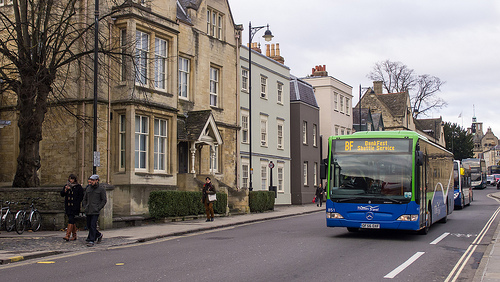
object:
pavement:
[2, 200, 322, 252]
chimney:
[372, 79, 385, 96]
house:
[335, 77, 437, 137]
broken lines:
[383, 250, 427, 277]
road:
[35, 243, 307, 281]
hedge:
[250, 188, 276, 213]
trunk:
[10, 100, 46, 187]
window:
[260, 73, 269, 100]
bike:
[0, 198, 17, 234]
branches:
[7, 13, 145, 81]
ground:
[394, 95, 423, 135]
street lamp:
[247, 23, 274, 191]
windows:
[206, 1, 225, 40]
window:
[259, 111, 270, 147]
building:
[235, 21, 295, 211]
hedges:
[145, 188, 229, 219]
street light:
[249, 22, 276, 46]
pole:
[247, 43, 255, 193]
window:
[136, 28, 153, 85]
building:
[469, 101, 499, 179]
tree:
[3, 18, 100, 215]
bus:
[322, 130, 457, 236]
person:
[201, 177, 218, 222]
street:
[94, 127, 408, 280]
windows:
[117, 111, 127, 172]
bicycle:
[15, 202, 44, 234]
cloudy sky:
[228, 0, 498, 129]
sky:
[429, 0, 497, 81]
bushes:
[148, 191, 226, 215]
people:
[82, 172, 107, 248]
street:
[112, 245, 474, 278]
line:
[432, 230, 452, 248]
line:
[477, 211, 498, 241]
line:
[451, 245, 476, 269]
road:
[304, 226, 402, 278]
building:
[292, 75, 324, 202]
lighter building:
[239, 45, 298, 194]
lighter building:
[307, 71, 359, 145]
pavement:
[4, 203, 154, 263]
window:
[240, 113, 251, 147]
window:
[242, 164, 250, 192]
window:
[134, 111, 150, 171]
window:
[259, 158, 273, 192]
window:
[277, 79, 284, 105]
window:
[278, 117, 286, 149]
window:
[276, 159, 285, 193]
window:
[302, 160, 309, 186]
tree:
[372, 61, 445, 101]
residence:
[6, 2, 246, 222]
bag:
[207, 193, 217, 202]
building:
[0, 0, 235, 221]